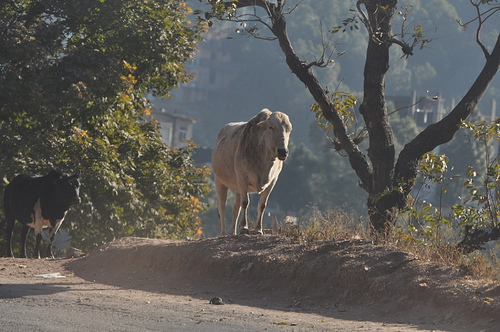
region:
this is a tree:
[11, 0, 137, 116]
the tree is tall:
[21, 16, 147, 126]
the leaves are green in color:
[97, 156, 144, 201]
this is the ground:
[128, 242, 183, 283]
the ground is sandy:
[132, 234, 193, 273]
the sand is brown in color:
[31, 253, 56, 275]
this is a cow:
[14, 168, 92, 255]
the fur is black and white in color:
[16, 188, 53, 217]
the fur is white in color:
[221, 125, 242, 154]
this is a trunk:
[374, 163, 412, 205]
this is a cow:
[178, 85, 324, 242]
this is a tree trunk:
[268, 23, 376, 185]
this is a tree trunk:
[352, 12, 398, 186]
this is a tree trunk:
[394, 28, 492, 208]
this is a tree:
[264, 0, 499, 267]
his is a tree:
[0, 0, 213, 261]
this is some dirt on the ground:
[24, 259, 102, 322]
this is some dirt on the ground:
[158, 225, 242, 293]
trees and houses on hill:
[182, 3, 493, 230]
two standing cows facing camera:
[6, 107, 295, 258]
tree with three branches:
[254, 2, 499, 239]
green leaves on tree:
[6, 0, 207, 238]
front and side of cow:
[213, 107, 292, 236]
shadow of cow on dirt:
[0, 277, 120, 304]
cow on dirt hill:
[82, 106, 429, 321]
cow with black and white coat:
[1, 167, 83, 258]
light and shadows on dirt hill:
[79, 230, 493, 322]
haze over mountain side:
[169, 1, 497, 233]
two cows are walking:
[0, 100, 341, 253]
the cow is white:
[182, 78, 320, 240]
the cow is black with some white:
[0, 155, 95, 237]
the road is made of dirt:
[5, 243, 82, 283]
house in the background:
[85, 85, 200, 175]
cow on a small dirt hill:
[170, 101, 332, 291]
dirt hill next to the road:
[175, 232, 340, 322]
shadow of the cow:
[0, 271, 124, 301]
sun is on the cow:
[237, 100, 311, 203]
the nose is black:
[267, 141, 292, 163]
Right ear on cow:
[252, 114, 269, 130]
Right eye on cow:
[265, 120, 276, 135]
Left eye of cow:
[285, 123, 295, 136]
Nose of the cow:
[275, 146, 292, 163]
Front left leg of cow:
[251, 186, 273, 226]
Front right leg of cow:
[232, 176, 249, 227]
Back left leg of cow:
[227, 184, 244, 235]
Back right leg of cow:
[209, 177, 234, 234]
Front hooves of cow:
[241, 223, 266, 239]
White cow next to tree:
[199, 96, 294, 243]